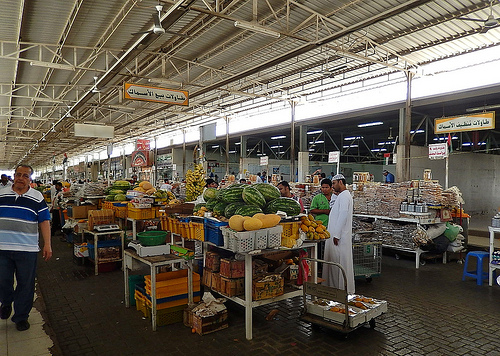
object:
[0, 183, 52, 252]
shirt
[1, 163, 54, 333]
man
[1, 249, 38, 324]
dark pants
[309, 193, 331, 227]
green shirt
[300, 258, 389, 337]
dolley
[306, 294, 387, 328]
items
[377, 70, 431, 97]
ground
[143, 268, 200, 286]
crate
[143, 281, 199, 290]
crate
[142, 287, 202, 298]
crate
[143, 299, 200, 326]
crate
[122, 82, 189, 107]
sign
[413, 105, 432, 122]
ground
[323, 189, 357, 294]
gown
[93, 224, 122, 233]
scale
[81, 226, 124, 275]
table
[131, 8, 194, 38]
fan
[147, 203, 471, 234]
stool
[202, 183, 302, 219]
watermelons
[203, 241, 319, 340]
table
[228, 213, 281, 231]
mangoes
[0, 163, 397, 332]
people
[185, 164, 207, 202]
bananas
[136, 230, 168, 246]
bowl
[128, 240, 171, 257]
scale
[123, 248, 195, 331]
table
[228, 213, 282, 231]
canteloupe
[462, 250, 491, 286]
stool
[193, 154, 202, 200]
rack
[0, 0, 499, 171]
ceiling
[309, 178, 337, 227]
woman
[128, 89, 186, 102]
writing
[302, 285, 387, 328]
packages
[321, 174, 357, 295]
he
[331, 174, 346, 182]
cap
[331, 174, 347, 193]
man's head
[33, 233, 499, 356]
floor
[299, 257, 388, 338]
cart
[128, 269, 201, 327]
containers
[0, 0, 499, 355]
market